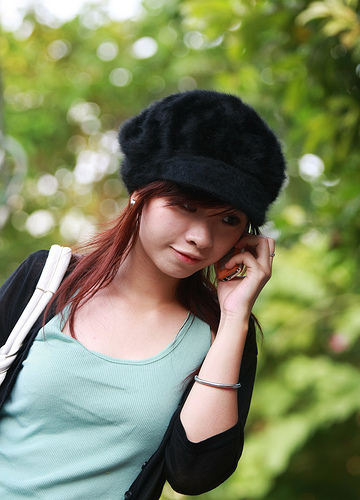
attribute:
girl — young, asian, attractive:
[0, 86, 295, 497]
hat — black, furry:
[118, 84, 295, 229]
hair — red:
[41, 182, 156, 342]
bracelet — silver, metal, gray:
[189, 374, 247, 393]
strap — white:
[36, 244, 75, 381]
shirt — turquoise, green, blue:
[0, 292, 220, 495]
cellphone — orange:
[220, 230, 267, 283]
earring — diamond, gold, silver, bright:
[124, 187, 142, 209]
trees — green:
[15, 17, 344, 94]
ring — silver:
[266, 251, 280, 261]